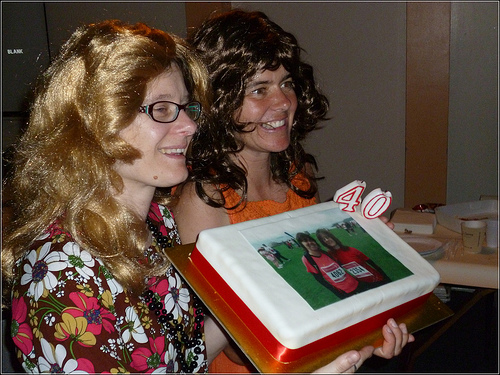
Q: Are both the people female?
A: Yes, all the people are female.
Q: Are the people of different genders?
A: No, all the people are female.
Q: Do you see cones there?
A: No, there are no cones.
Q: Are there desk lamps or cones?
A: No, there are no cones or desk lamps.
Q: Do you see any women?
A: Yes, there is a woman.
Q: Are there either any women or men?
A: Yes, there is a woman.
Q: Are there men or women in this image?
A: Yes, there is a woman.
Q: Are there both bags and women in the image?
A: No, there is a woman but no bags.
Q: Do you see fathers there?
A: No, there are no fathers.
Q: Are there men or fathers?
A: No, there are no fathers or men.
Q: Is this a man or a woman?
A: This is a woman.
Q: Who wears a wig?
A: The woman wears a wig.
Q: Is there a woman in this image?
A: Yes, there is a woman.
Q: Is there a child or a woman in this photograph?
A: Yes, there is a woman.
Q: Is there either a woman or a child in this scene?
A: Yes, there is a woman.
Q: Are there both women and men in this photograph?
A: No, there is a woman but no men.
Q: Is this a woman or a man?
A: This is a woman.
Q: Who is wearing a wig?
A: The woman is wearing a wig.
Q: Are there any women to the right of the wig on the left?
A: Yes, there is a woman to the right of the wig.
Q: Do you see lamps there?
A: No, there are no lamps.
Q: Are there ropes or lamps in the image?
A: No, there are no lamps or ropes.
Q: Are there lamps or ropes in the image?
A: No, there are no lamps or ropes.